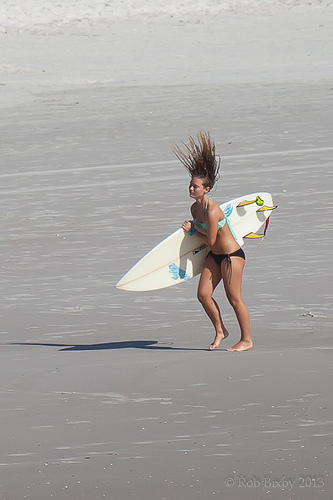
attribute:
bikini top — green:
[192, 218, 224, 232]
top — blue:
[180, 202, 231, 233]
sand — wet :
[1, 215, 328, 498]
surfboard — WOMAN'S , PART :
[115, 189, 273, 291]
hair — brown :
[170, 128, 222, 192]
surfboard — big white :
[105, 186, 276, 303]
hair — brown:
[162, 126, 228, 197]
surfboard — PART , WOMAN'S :
[138, 268, 162, 283]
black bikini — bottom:
[190, 208, 248, 263]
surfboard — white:
[104, 239, 208, 301]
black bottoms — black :
[208, 247, 247, 264]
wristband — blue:
[185, 221, 195, 238]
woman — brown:
[134, 139, 290, 355]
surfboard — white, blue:
[117, 198, 276, 295]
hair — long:
[167, 131, 219, 190]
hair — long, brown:
[169, 124, 223, 189]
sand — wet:
[6, 4, 328, 492]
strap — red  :
[247, 213, 276, 245]